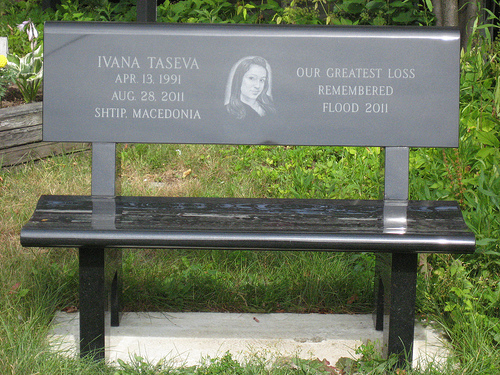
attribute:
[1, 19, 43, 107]
flowers — growing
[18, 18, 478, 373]
bench — shiny, grey, stone, outdoor, dark grey, light grey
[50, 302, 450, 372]
slab — cement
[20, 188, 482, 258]
seat — black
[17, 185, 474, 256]
bench — metallic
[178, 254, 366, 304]
grass — green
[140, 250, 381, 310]
grass — long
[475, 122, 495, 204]
leaves — green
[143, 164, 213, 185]
grass — dry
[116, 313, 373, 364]
floor — cemented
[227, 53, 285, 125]
hair — long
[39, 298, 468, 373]
cement slab — cement 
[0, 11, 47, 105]
plants — yellow , white 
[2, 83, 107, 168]
planter — wooden 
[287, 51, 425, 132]
text — grey 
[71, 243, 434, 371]
supports — legs